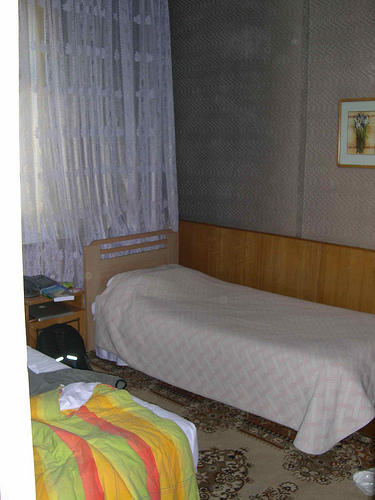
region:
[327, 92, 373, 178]
portrait hanging on wall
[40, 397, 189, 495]
striped bedspread on bed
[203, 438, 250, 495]
design on oriental carpet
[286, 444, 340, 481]
design on oriental carpet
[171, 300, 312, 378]
bedspread on twin bed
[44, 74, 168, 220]
sheer white long curtain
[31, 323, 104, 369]
black book bag on floor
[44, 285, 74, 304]
book on night stand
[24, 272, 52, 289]
black phone on nightstand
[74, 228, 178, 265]
wooden headboard against wall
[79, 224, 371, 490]
Twin bed with a blanket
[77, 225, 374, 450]
Blanket on twin bed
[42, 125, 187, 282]
Lace curtains on the window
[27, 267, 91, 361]
Wooden stand by the bed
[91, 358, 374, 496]
Rug on the floor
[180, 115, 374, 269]
Wall paper in the bedroom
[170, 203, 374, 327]
Wood panelling in a bedroom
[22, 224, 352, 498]
Two twin beds in a room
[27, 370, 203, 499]
Striped blanket on a bed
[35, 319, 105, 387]
Backpack on the floor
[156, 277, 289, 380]
bed comforter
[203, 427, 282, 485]
rug on the floor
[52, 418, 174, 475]
a colorful comforter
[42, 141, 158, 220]
curtains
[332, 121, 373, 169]
a picture on the wall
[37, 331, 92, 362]
a bag on the floor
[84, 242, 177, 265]
the head board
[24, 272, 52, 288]
a telephone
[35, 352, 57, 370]
white sheets on the bed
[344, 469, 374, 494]
object on the rug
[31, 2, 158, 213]
White lace curtains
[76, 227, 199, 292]
A wooden headboard on a bed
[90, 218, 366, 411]
A bed positioned against the wall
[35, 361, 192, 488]
Colorful striped blanket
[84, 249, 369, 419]
A twin bed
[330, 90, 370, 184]
Framed artwork on a wall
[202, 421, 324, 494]
Carpeting in neutral tones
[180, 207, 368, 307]
Brown wooden wainscoting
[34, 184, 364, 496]
A bedroom with two beds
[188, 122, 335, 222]
Patterned gray wallpaper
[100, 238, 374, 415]
A twin bed in the room.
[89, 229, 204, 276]
The headboard is wooden.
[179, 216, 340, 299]
The side panel on the bed is wooden.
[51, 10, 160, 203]
A white curtain covering the window.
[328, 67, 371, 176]
A painting on the wall.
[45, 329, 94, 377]
A bookbag is on the floor.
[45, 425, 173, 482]
A green and yellow comforter on the bed.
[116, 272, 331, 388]
The spread is covering the pillow.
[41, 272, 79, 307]
A book on the nightstand.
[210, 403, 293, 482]
The rug has a flowery design.